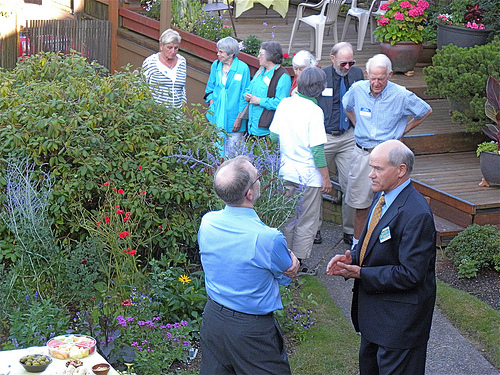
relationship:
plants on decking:
[470, 136, 500, 202] [385, 144, 500, 253]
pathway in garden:
[306, 223, 496, 373] [0, 47, 297, 373]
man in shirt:
[338, 139, 428, 372] [195, 204, 286, 314]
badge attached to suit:
[376, 222, 400, 243] [351, 184, 451, 373]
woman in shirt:
[144, 15, 191, 130] [140, 55, 194, 108]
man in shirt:
[185, 160, 305, 374] [198, 203, 281, 307]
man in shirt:
[337, 48, 435, 256] [335, 75, 432, 158]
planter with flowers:
[373, 36, 423, 75] [372, 0, 426, 42]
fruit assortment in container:
[50, 333, 93, 349] [45, 332, 97, 359]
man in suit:
[357, 136, 427, 228] [351, 185, 448, 332]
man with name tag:
[337, 51, 432, 146] [355, 105, 375, 120]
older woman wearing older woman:
[203, 37, 252, 146] [139, 30, 188, 106]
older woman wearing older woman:
[203, 37, 252, 146] [249, 40, 292, 137]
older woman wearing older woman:
[203, 37, 252, 146] [289, 50, 315, 82]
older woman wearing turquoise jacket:
[203, 37, 252, 146] [206, 58, 248, 135]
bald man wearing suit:
[330, 136, 440, 372] [304, 186, 478, 373]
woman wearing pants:
[266, 65, 333, 277] [279, 176, 321, 260]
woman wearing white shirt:
[266, 65, 333, 277] [268, 93, 329, 186]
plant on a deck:
[375, 9, 425, 44] [394, 71, 441, 93]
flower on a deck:
[394, 12, 401, 21] [394, 71, 441, 93]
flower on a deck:
[378, 17, 388, 27] [394, 71, 441, 93]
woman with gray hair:
[121, 20, 207, 120] [158, 26, 184, 46]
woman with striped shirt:
[121, 20, 207, 120] [134, 50, 189, 110]